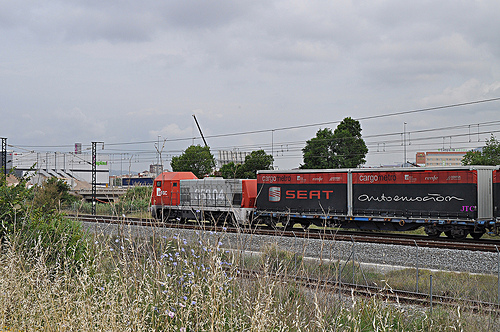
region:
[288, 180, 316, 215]
part of a train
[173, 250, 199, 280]
part of a grass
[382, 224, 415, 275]
part of a ground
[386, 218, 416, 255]
edge of a rail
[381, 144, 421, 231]
part of a train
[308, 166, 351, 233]
side of a train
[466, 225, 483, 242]
part of a wheel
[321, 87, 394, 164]
part of a trree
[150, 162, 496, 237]
The train has three total cars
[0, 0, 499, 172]
The sky is cloudy.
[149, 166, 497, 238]
The engine is pulling two cars.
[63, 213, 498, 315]
Three pairs of train rail.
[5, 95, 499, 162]
Electric wires are above ground.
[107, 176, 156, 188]
Blue building in front of red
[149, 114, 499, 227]
Four trees over train.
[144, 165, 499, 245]
The train is mostly orange and gray.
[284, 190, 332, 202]
Red letters o dark background.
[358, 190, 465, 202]
White cursive letters on dark surface.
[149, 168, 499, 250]
a red train pulling carts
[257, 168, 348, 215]
red and black cart that sys SERT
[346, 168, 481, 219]
a red and black car with white writing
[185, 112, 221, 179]
a leaning power pole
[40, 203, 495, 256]
a set of railroad tracks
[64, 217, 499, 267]
gravel around a train track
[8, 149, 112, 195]
a white structure in background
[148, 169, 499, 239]
train is on train tracks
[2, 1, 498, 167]
the sky has an overcast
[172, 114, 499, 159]
trees behind a train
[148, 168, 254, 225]
a red and silver train engine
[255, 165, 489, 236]
a red and black box car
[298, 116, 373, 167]
large green tree in distance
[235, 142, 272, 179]
large green tree in distance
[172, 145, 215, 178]
large green tree in distance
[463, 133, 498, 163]
large green tree in distance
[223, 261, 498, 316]
a set of train tracks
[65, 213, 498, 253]
a set of train tracks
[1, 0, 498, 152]
a grey cloudy sky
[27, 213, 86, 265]
a large green bush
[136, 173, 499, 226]
a long train on the track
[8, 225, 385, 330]
weeds with little flowers on it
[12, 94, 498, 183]
the power lines above the train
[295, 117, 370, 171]
a tree with a lot of green leaves on it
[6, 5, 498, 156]
the cloudy sky above the train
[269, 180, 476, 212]
the writing on the trains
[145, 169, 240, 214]
the engine of the train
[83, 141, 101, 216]
a metal pole next to the track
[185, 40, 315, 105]
a cloud in the sky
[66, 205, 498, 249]
the track for the train